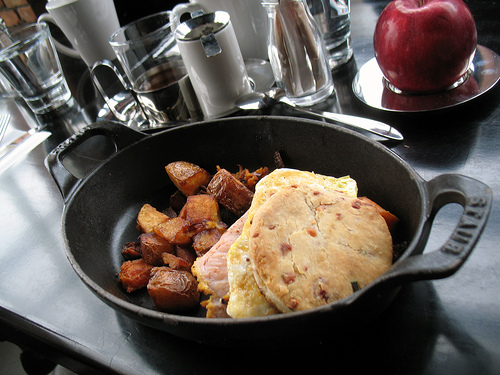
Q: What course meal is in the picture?
A: Breakfast.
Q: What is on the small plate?
A: An apple.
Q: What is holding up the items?
A: A table.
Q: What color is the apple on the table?
A: Red.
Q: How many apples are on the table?
A: One.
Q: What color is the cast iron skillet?
A: Black.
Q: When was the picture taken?
A: During the day.